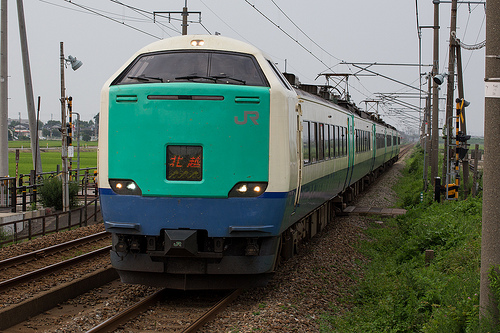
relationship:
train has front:
[93, 35, 405, 276] [98, 60, 302, 254]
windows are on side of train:
[300, 123, 389, 154] [93, 35, 405, 276]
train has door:
[93, 35, 405, 276] [343, 118, 359, 181]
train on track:
[93, 35, 405, 276] [376, 154, 424, 201]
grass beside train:
[8, 132, 101, 184] [93, 35, 405, 276]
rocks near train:
[387, 168, 404, 186] [93, 35, 405, 276]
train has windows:
[93, 35, 405, 276] [300, 123, 389, 154]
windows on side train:
[300, 123, 389, 154] [93, 35, 405, 276]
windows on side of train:
[300, 123, 389, 154] [93, 35, 405, 276]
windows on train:
[300, 123, 389, 154] [93, 35, 405, 276]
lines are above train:
[71, 1, 367, 102] [93, 35, 405, 276]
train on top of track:
[93, 35, 405, 276] [376, 154, 424, 201]